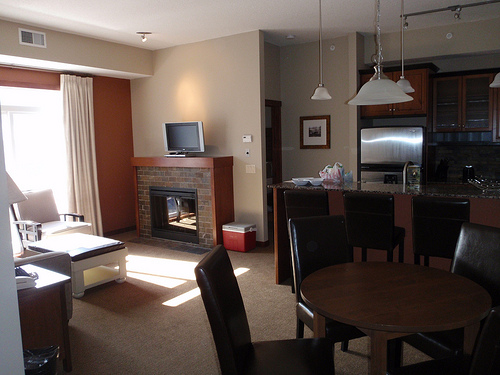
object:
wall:
[280, 32, 361, 184]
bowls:
[289, 178, 309, 186]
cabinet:
[437, 74, 492, 131]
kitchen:
[0, 2, 497, 375]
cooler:
[222, 222, 258, 252]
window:
[0, 85, 73, 198]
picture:
[303, 119, 327, 145]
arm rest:
[58, 213, 84, 222]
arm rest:
[15, 219, 43, 242]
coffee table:
[23, 226, 131, 298]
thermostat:
[242, 135, 251, 143]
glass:
[436, 79, 461, 127]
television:
[161, 121, 205, 156]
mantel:
[129, 150, 233, 171]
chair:
[341, 189, 406, 268]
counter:
[267, 175, 499, 200]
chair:
[5, 189, 94, 248]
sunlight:
[116, 232, 236, 313]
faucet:
[401, 158, 414, 180]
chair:
[192, 243, 334, 375]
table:
[298, 261, 494, 374]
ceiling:
[1, 2, 497, 51]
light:
[395, 1, 415, 93]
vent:
[19, 27, 46, 48]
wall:
[0, 20, 152, 79]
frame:
[12, 191, 94, 250]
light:
[343, 0, 414, 107]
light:
[304, 0, 335, 102]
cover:
[346, 75, 414, 107]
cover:
[309, 85, 332, 101]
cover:
[394, 79, 416, 95]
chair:
[286, 214, 365, 361]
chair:
[446, 225, 498, 374]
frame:
[300, 115, 331, 149]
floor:
[69, 240, 293, 375]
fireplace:
[134, 159, 214, 247]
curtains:
[60, 73, 108, 237]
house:
[0, 0, 499, 375]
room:
[0, 8, 493, 374]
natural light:
[8, 86, 160, 291]